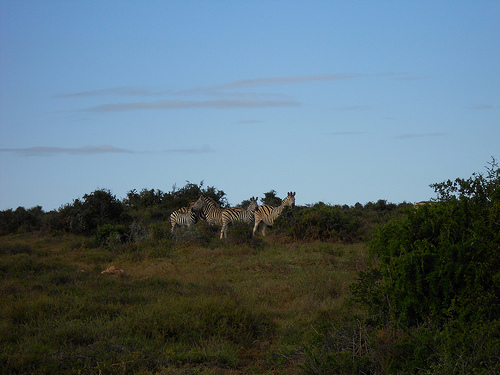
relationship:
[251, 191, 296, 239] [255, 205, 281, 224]
zebra has stripes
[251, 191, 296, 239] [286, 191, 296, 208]
zebra has head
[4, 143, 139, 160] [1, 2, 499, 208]
cloud in sky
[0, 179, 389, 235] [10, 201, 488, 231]
trees in background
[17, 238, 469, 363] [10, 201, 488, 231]
field has background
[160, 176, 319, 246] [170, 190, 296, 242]
herd of zebras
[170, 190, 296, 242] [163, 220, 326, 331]
zebras in grass